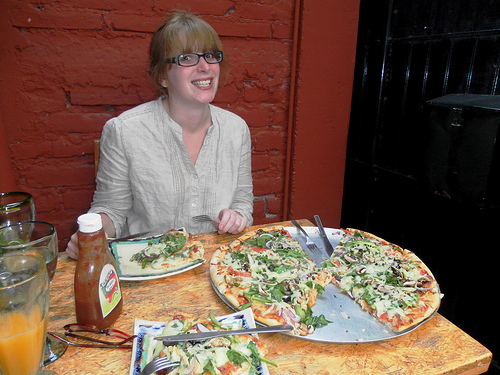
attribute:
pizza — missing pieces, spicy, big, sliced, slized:
[211, 223, 442, 338]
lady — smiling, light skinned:
[65, 11, 255, 259]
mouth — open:
[194, 78, 214, 90]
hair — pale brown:
[151, 12, 224, 79]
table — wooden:
[2, 219, 494, 374]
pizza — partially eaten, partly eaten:
[129, 227, 205, 269]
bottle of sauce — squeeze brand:
[75, 213, 124, 333]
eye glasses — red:
[63, 320, 138, 350]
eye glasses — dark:
[167, 49, 223, 67]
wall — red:
[0, 0, 362, 224]